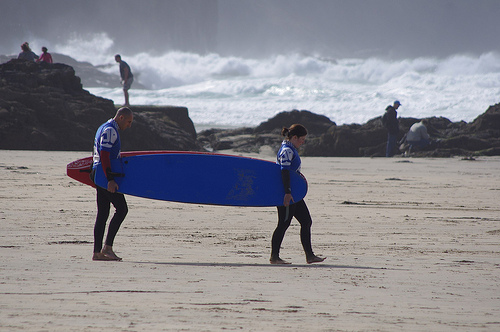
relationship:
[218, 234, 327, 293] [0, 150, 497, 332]
floor covered in beach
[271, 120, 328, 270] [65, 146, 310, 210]
person carrying surfboard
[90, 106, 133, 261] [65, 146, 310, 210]
man carrying surfboard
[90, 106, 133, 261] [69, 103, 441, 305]
man carrying surfboard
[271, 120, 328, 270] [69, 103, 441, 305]
person carrying surfboard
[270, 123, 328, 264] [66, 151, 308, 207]
person carrying surfboard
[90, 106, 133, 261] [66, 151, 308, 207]
man carrying surfboard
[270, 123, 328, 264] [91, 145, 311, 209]
person carrying surf board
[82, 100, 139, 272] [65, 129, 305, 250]
man carrying surfboard